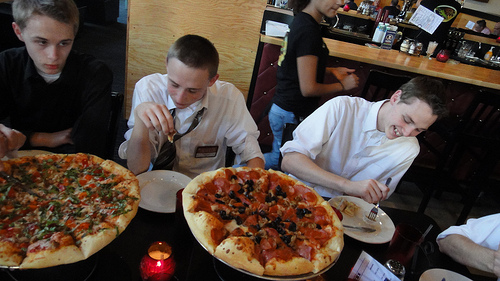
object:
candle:
[436, 49, 450, 62]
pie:
[0, 150, 142, 271]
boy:
[0, 0, 112, 159]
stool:
[416, 90, 500, 226]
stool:
[361, 69, 414, 102]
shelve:
[261, 0, 500, 71]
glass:
[386, 224, 424, 264]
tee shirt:
[0, 46, 113, 154]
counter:
[321, 38, 500, 90]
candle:
[139, 240, 176, 280]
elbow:
[437, 233, 477, 256]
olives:
[275, 184, 287, 198]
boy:
[279, 77, 449, 204]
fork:
[367, 177, 393, 220]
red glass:
[139, 242, 176, 281]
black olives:
[288, 222, 297, 232]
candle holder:
[138, 268, 176, 278]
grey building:
[350, 49, 475, 68]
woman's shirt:
[270, 22, 329, 118]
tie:
[151, 107, 204, 171]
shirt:
[118, 73, 266, 179]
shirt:
[279, 76, 452, 204]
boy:
[118, 34, 264, 176]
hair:
[398, 76, 450, 120]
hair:
[167, 34, 220, 84]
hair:
[12, 0, 80, 35]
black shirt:
[0, 46, 112, 159]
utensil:
[342, 224, 376, 233]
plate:
[324, 192, 400, 243]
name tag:
[194, 146, 218, 159]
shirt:
[272, 10, 329, 115]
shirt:
[436, 212, 500, 252]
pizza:
[181, 167, 344, 276]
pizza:
[0, 149, 140, 269]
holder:
[137, 239, 177, 279]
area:
[0, 0, 128, 146]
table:
[0, 196, 478, 281]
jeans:
[232, 103, 299, 170]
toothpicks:
[400, 39, 412, 53]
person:
[232, 0, 360, 170]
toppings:
[2, 154, 125, 248]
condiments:
[399, 37, 425, 57]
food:
[332, 197, 360, 216]